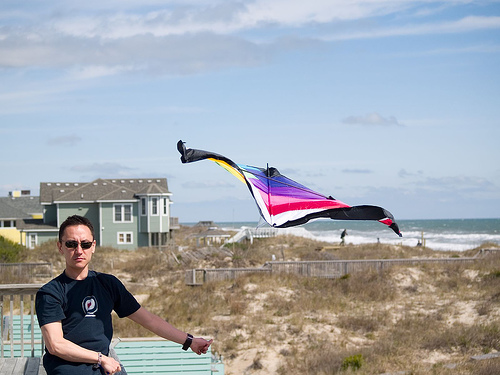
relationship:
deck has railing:
[7, 318, 196, 374] [4, 282, 63, 362]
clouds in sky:
[8, 2, 497, 102] [1, 0, 498, 221]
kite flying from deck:
[176, 139, 403, 239] [7, 282, 224, 371]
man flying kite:
[30, 214, 210, 373] [178, 136, 408, 248]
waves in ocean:
[324, 226, 497, 249] [404, 219, 498, 234]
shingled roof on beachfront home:
[43, 179, 165, 202] [0, 176, 182, 250]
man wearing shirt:
[34, 214, 216, 375] [33, 271, 138, 365]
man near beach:
[34, 214, 216, 375] [171, 217, 490, 253]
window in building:
[113, 204, 133, 223] [19, 177, 174, 252]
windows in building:
[114, 229, 135, 246] [13, 170, 182, 252]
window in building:
[149, 195, 161, 217] [35, 173, 177, 250]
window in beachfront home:
[111, 204, 136, 225] [0, 176, 182, 250]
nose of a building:
[136, 178, 175, 238] [1, 172, 187, 255]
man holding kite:
[34, 214, 216, 375] [170, 129, 417, 249]